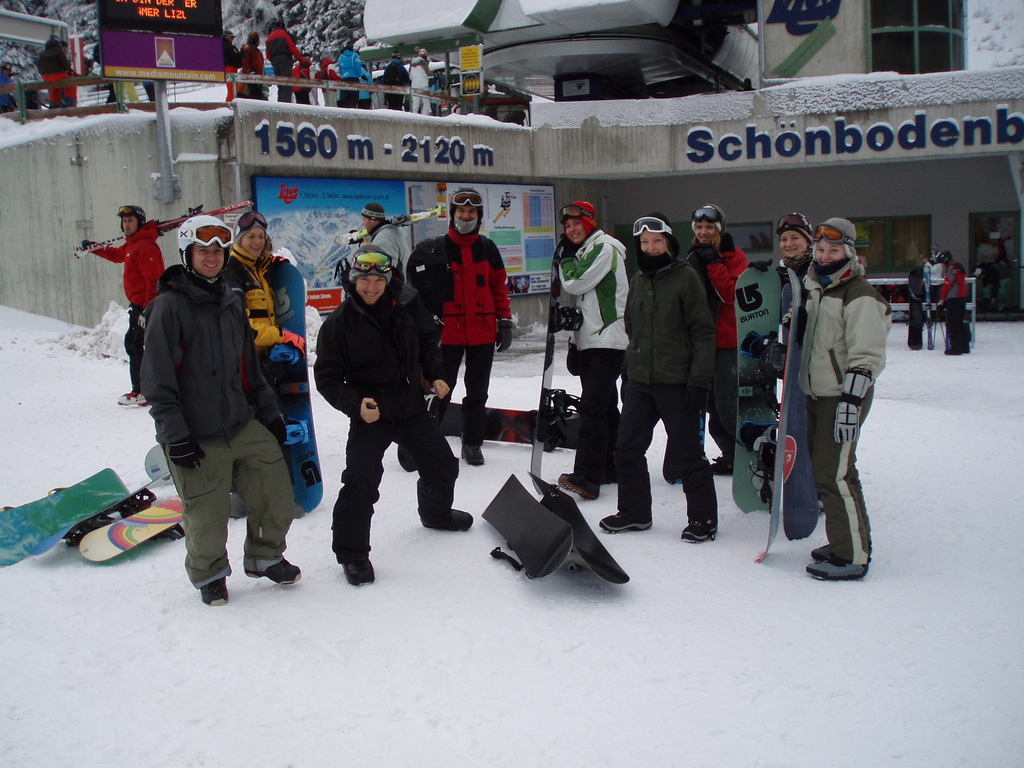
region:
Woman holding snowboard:
[779, 213, 893, 588]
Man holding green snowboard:
[735, 208, 813, 515]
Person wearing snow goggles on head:
[599, 211, 724, 551]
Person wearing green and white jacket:
[536, 198, 632, 511]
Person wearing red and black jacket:
[403, 183, 522, 471]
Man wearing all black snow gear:
[314, 248, 476, 597]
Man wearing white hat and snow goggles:
[135, 211, 306, 611]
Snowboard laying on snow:
[68, 480, 189, 567]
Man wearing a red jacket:
[75, 201, 178, 417]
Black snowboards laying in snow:
[479, 464, 629, 589]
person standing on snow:
[744, 209, 824, 521]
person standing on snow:
[664, 200, 746, 481]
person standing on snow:
[593, 209, 722, 543]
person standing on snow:
[549, 200, 629, 505]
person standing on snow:
[404, 184, 517, 471]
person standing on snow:
[337, 204, 419, 306]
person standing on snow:
[311, 241, 477, 593]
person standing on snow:
[141, 211, 303, 602]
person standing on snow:
[227, 209, 309, 519]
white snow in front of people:
[351, 623, 573, 757]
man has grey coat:
[798, 293, 871, 412]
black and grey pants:
[798, 404, 844, 523]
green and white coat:
[482, 216, 660, 394]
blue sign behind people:
[669, 111, 1017, 169]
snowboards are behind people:
[0, 480, 175, 591]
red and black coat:
[403, 237, 517, 380]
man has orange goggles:
[187, 222, 225, 254]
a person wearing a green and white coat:
[557, 237, 628, 351]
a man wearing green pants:
[188, 427, 287, 583]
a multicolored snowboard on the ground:
[77, 497, 179, 578]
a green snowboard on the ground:
[0, 468, 128, 557]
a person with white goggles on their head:
[629, 216, 672, 240]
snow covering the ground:
[218, 623, 920, 766]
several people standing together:
[146, 177, 887, 595]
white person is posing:
[140, 217, 302, 610]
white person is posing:
[232, 213, 294, 469]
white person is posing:
[317, 245, 477, 597]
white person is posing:
[423, 194, 507, 466]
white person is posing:
[561, 201, 629, 493]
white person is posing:
[602, 215, 721, 541]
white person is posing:
[690, 205, 751, 475]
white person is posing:
[762, 215, 821, 516]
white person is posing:
[781, 220, 886, 582]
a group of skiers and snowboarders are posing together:
[138, 188, 892, 603]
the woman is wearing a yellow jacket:
[227, 207, 325, 518]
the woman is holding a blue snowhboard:
[265, 256, 326, 514]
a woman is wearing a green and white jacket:
[527, 200, 626, 492]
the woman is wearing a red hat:
[535, 194, 622, 499]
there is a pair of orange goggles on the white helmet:
[175, 222, 237, 246]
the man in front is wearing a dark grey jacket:
[141, 266, 275, 441]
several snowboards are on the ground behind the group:
[4, 465, 188, 565]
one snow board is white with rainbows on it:
[80, 493, 189, 560]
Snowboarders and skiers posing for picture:
[124, 181, 921, 612]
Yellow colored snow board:
[76, 492, 194, 568]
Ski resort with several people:
[0, 3, 1021, 766]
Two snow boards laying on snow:
[469, 462, 628, 600]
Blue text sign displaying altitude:
[239, 119, 500, 177]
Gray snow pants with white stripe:
[800, 389, 881, 566]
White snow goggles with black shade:
[624, 214, 678, 244]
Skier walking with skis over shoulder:
[67, 200, 260, 410]